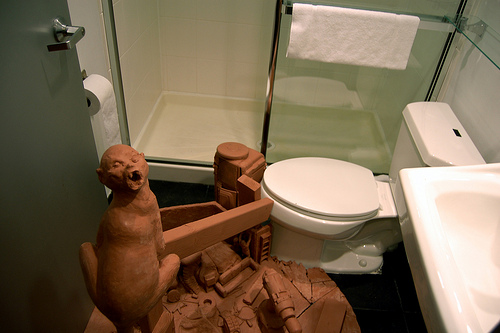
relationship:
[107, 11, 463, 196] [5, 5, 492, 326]
shower in bathroom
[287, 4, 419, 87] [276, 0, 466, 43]
towel in hanger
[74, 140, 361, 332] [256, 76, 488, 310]
carving in tiolet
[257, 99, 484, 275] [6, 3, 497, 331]
toilet in image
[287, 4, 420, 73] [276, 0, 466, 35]
towel on hanger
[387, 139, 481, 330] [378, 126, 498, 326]
edge on sink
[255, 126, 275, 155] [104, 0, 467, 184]
drain in shower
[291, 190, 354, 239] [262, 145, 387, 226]
edge of lid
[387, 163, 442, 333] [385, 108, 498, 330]
edge of sink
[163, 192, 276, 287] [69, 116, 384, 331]
part of statue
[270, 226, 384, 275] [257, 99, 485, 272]
side belonging to toilet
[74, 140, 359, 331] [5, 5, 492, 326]
carving sitting inside bathroom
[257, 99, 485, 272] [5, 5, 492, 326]
toilet sitting inside bathroom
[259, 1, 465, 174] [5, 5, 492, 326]
shower door mounted in bathroom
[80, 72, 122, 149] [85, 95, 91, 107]
toilet paper wrapped around roll